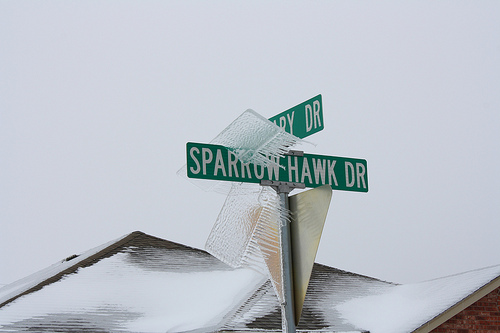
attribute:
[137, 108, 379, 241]
street signs — green, named, at intersection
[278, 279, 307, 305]
pole — gray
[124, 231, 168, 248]
roof — black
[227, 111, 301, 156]
ice — melting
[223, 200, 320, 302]
sign — triangle